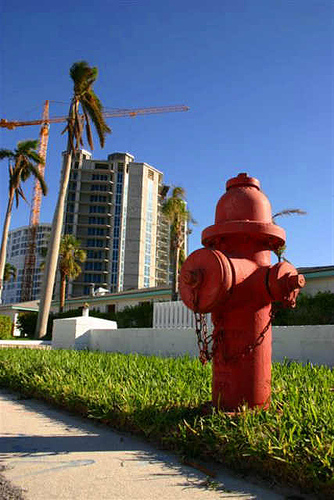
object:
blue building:
[52, 148, 188, 318]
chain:
[193, 305, 281, 366]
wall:
[55, 332, 326, 358]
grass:
[0, 345, 334, 495]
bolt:
[179, 171, 306, 410]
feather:
[272, 208, 308, 219]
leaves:
[0, 139, 48, 211]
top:
[61, 61, 113, 158]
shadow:
[142, 400, 212, 436]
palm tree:
[32, 59, 111, 339]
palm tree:
[0, 137, 48, 292]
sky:
[2, 2, 331, 264]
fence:
[152, 300, 213, 327]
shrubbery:
[269, 290, 333, 326]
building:
[52, 266, 334, 369]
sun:
[0, 461, 173, 497]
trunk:
[32, 154, 72, 340]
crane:
[0, 99, 190, 303]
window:
[15, 250, 18, 255]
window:
[7, 284, 10, 290]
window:
[43, 226, 46, 231]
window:
[14, 232, 16, 237]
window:
[16, 289, 19, 295]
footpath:
[0, 389, 307, 498]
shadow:
[0, 436, 136, 453]